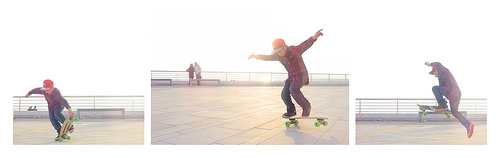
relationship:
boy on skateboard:
[247, 29, 325, 117] [280, 111, 330, 129]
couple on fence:
[182, 62, 204, 85] [363, 90, 421, 118]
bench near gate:
[70, 104, 126, 118] [12, 92, 144, 112]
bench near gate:
[417, 103, 468, 125] [355, 100, 487, 118]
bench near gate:
[150, 76, 175, 86] [153, 68, 351, 89]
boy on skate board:
[425, 61, 475, 138] [412, 97, 468, 120]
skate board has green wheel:
[285, 117, 328, 127] [314, 119, 321, 127]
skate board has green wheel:
[283, 113, 327, 119] [284, 120, 299, 125]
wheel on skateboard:
[63, 118, 73, 124] [52, 110, 80, 149]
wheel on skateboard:
[55, 136, 65, 151] [52, 110, 80, 149]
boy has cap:
[247, 25, 329, 117] [271, 38, 286, 54]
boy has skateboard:
[24, 77, 78, 134] [56, 110, 76, 141]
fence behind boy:
[355, 95, 488, 123] [425, 60, 476, 137]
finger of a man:
[317, 27, 322, 36] [249, 24, 326, 114]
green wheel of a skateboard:
[314, 122, 321, 128] [273, 107, 338, 131]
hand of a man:
[245, 51, 260, 61] [263, 29, 298, 67]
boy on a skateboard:
[24, 79, 77, 141] [55, 111, 76, 140]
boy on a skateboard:
[247, 29, 325, 117] [458, 110, 481, 150]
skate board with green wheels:
[285, 117, 328, 127] [283, 117, 329, 125]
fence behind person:
[150, 70, 347, 84] [268, 20, 344, 128]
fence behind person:
[355, 96, 488, 123] [413, 60, 475, 138]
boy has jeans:
[247, 29, 325, 117] [279, 78, 313, 113]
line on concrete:
[13, 114, 53, 143] [13, 108, 487, 142]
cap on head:
[271, 36, 287, 51] [270, 36, 289, 59]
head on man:
[270, 36, 289, 59] [245, 27, 331, 121]